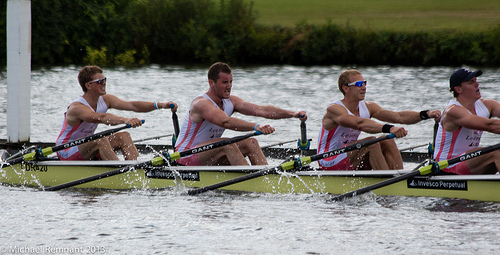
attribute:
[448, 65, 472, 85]
hat — black 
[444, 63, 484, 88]
hat — black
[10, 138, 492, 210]
boats — green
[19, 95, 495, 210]
oars — black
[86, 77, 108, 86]
sunglasses — white 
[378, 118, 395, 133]
sweatbands — black 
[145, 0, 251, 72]
bush — green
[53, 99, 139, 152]
shirt — white, red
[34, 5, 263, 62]
bushes — Large 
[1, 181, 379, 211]
wake — small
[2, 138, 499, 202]
boat — yellow, black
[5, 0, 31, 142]
pole — white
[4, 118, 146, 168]
oar — black, yellow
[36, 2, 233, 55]
trees — gree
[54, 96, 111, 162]
uniform — white, orange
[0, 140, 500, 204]
row boat — green , Large 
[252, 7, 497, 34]
grass — growing 